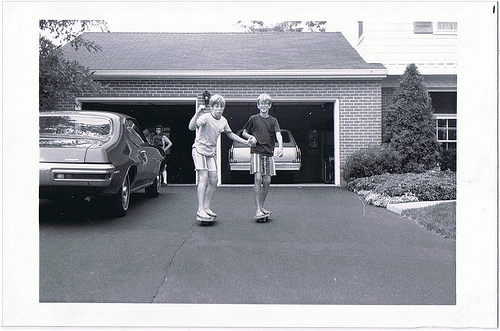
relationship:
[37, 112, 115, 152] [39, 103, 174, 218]
window on car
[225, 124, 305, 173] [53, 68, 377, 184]
car in garage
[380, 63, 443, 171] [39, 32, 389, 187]
pine tree next garage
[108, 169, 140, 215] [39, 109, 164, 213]
tire on car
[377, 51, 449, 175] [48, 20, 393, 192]
pine tree next garage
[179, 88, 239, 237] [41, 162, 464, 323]
boy in driveway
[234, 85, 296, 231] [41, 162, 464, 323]
boy in driveway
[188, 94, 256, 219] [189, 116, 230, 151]
boy wearing tshirt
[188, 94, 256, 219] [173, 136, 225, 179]
boy wearing shorts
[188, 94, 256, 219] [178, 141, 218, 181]
boy wearing shorts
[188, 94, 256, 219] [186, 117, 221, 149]
boy wearing tshirt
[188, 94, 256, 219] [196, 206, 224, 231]
boy on skateboards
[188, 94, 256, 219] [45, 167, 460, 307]
boy in driveway